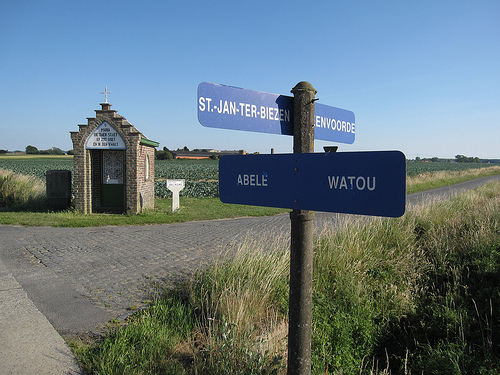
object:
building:
[69, 86, 159, 214]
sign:
[219, 150, 405, 218]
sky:
[0, 0, 499, 159]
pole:
[286, 81, 316, 375]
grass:
[66, 176, 500, 374]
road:
[0, 175, 499, 374]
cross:
[100, 86, 114, 103]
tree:
[25, 145, 39, 154]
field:
[0, 154, 500, 375]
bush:
[0, 167, 47, 212]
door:
[100, 149, 125, 212]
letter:
[328, 176, 375, 191]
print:
[237, 174, 267, 187]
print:
[198, 96, 355, 133]